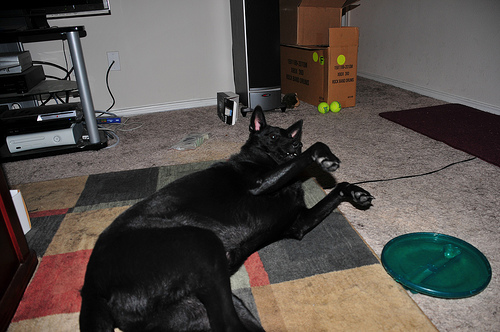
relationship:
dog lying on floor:
[80, 108, 375, 328] [11, 106, 498, 327]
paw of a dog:
[331, 173, 373, 210] [80, 108, 375, 328]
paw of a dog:
[312, 140, 341, 172] [80, 108, 375, 328]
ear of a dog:
[251, 106, 264, 133] [80, 108, 375, 328]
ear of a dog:
[288, 116, 305, 139] [80, 108, 375, 328]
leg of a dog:
[287, 191, 340, 241] [42, 126, 391, 313]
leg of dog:
[253, 140, 340, 195] [80, 108, 375, 328]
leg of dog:
[298, 180, 372, 240] [80, 108, 375, 328]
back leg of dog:
[141, 226, 245, 332] [80, 108, 375, 328]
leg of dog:
[136, 297, 203, 325] [80, 108, 375, 328]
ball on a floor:
[329, 100, 341, 112] [2, 76, 497, 326]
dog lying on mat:
[80, 108, 375, 328] [6, 147, 441, 330]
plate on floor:
[380, 230, 493, 300] [2, 76, 497, 326]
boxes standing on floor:
[275, 0, 367, 102] [355, 101, 421, 180]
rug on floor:
[37, 164, 184, 286] [371, 184, 440, 225]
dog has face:
[80, 108, 375, 328] [255, 122, 305, 157]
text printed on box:
[331, 60, 356, 86] [279, 22, 362, 107]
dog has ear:
[77, 104, 376, 331] [245, 96, 274, 138]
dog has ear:
[80, 108, 375, 328] [246, 105, 266, 132]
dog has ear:
[80, 108, 375, 328] [286, 116, 304, 138]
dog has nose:
[80, 108, 375, 328] [275, 142, 299, 159]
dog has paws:
[80, 108, 375, 328] [311, 146, 370, 207]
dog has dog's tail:
[80, 108, 375, 328] [76, 291, 117, 332]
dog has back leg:
[77, 104, 376, 331] [141, 215, 246, 324]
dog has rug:
[77, 104, 376, 331] [0, 161, 436, 327]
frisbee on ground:
[383, 214, 498, 316] [2, 68, 493, 327]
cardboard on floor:
[291, 39, 364, 109] [2, 76, 497, 326]